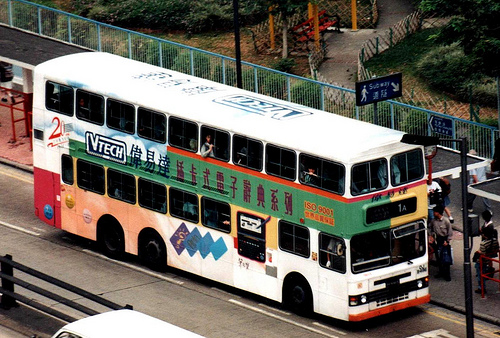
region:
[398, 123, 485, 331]
Tall black light pole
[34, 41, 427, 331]
The bus is on the side of the street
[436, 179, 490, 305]
People standing on the side walk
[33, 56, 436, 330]
The bus has two decks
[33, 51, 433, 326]
Bus is white, green and red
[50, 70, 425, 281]
Bus has many windows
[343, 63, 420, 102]
Blue, black and white sign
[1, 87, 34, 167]
Red brick walk way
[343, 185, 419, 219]
Black sign on front of bus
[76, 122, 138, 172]
Letters say Vtech on side of bus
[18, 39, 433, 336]
A double-decker bus is on a road.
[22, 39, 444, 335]
The colors of a double-decker bus are white, red, pink, orange, green, and black.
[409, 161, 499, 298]
People are next to a bus.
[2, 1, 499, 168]
A blue metal fence is behind a bus.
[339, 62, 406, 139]
A sign is behind a bus.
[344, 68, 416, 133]
The color of a sign is blue and white.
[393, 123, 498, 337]
A lamppost is next to a bus.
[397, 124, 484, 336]
The color of a lamppost is black.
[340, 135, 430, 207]
A person is at the front of a bus.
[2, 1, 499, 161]
Green bushes are in the background.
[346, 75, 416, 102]
street sign on the roadside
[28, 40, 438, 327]
a two story bus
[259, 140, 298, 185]
a window on the bus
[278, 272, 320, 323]
a wheel on the bus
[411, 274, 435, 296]
a head light on the bus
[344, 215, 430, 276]
the windshield of the bus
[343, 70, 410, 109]
a blue and white sign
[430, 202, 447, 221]
the head of a man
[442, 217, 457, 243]
the arm of a man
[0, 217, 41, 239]
a white stripe on the street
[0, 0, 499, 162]
a blue fence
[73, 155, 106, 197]
black bus window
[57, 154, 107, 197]
two black bus windows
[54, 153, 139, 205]
three black bus windows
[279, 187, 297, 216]
purple asian character on bus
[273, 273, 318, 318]
black front wheel on the bus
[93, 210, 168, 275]
two black wheels on the bus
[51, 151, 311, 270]
row of bus windows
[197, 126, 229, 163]
passenger on the double decker bus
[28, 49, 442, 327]
colorful double decker bus on the street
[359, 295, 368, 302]
white light on the front of a bus